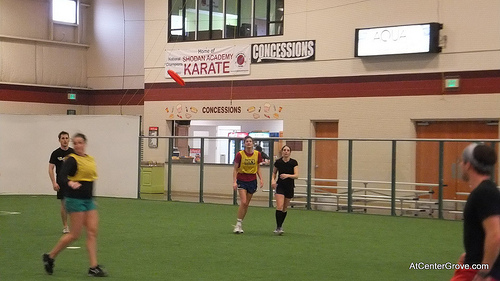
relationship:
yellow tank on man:
[235, 149, 261, 179] [228, 133, 263, 235]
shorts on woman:
[56, 193, 100, 215] [29, 125, 107, 276]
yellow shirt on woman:
[69, 153, 114, 188] [57, 131, 113, 266]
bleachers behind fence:
[261, 175, 446, 217] [138, 133, 498, 218]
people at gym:
[41, 120, 108, 279] [8, 9, 493, 264]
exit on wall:
[429, 64, 478, 105] [286, 21, 464, 244]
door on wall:
[311, 119, 341, 199] [145, 8, 497, 192]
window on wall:
[165, 120, 234, 165] [139, 105, 266, 204]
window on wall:
[168, 0, 287, 42] [194, 46, 454, 186]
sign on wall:
[160, 47, 262, 81] [157, 34, 322, 84]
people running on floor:
[41, 132, 109, 280] [1, 193, 466, 279]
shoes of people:
[271, 225, 287, 238] [267, 145, 299, 235]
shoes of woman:
[228, 217, 248, 234] [230, 135, 265, 237]